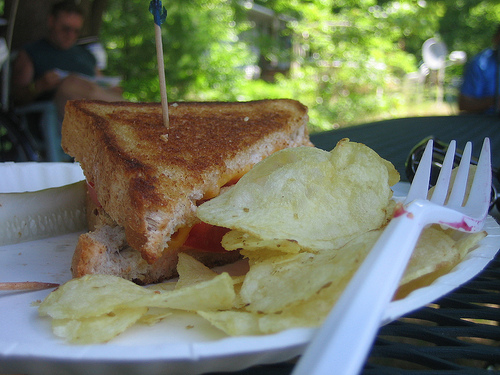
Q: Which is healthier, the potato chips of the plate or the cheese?
A: The cheese is healthier than the potato chips.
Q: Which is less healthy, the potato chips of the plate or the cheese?
A: The potato chips is less healthy than the cheese.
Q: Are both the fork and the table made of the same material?
A: No, the fork is made of plastic and the table is made of metal.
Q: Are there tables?
A: Yes, there is a table.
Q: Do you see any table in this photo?
A: Yes, there is a table.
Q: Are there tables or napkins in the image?
A: Yes, there is a table.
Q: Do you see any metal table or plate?
A: Yes, there is a metal table.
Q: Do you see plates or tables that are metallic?
A: Yes, the table is metallic.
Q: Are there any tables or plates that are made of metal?
A: Yes, the table is made of metal.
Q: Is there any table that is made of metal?
A: Yes, there is a table that is made of metal.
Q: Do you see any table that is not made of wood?
A: Yes, there is a table that is made of metal.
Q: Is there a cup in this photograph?
A: No, there are no cups.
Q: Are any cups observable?
A: No, there are no cups.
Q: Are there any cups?
A: No, there are no cups.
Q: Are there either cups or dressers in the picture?
A: No, there are no cups or dressers.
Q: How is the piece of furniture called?
A: The piece of furniture is a table.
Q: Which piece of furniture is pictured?
A: The piece of furniture is a table.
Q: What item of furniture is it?
A: The piece of furniture is a table.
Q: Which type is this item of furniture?
A: That is a table.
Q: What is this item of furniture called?
A: That is a table.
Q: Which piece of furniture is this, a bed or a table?
A: That is a table.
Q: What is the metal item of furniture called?
A: The piece of furniture is a table.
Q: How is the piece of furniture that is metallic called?
A: The piece of furniture is a table.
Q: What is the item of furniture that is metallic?
A: The piece of furniture is a table.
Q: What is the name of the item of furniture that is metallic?
A: The piece of furniture is a table.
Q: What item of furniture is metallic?
A: The piece of furniture is a table.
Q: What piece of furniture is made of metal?
A: The piece of furniture is a table.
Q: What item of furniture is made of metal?
A: The piece of furniture is a table.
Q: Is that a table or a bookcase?
A: That is a table.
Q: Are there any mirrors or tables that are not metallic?
A: No, there is a table but it is metallic.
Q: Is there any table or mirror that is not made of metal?
A: No, there is a table but it is made of metal.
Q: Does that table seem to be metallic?
A: Yes, the table is metallic.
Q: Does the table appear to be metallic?
A: Yes, the table is metallic.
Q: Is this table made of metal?
A: Yes, the table is made of metal.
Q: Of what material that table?
A: The table is made of metal.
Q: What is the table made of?
A: The table is made of metal.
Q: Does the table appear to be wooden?
A: No, the table is metallic.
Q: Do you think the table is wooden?
A: No, the table is metallic.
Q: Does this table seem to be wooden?
A: No, the table is metallic.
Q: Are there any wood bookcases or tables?
A: No, there is a table but it is metallic.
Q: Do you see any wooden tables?
A: No, there is a table but it is metallic.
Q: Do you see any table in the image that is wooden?
A: No, there is a table but it is metallic.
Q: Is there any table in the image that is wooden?
A: No, there is a table but it is metallic.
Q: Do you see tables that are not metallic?
A: No, there is a table but it is metallic.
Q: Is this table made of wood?
A: No, the table is made of metal.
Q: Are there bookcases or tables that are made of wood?
A: No, there is a table but it is made of metal.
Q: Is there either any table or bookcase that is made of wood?
A: No, there is a table but it is made of metal.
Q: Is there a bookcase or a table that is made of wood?
A: No, there is a table but it is made of metal.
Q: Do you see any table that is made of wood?
A: No, there is a table but it is made of metal.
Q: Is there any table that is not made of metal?
A: No, there is a table but it is made of metal.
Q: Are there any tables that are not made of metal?
A: No, there is a table but it is made of metal.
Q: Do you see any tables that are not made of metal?
A: No, there is a table but it is made of metal.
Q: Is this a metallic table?
A: Yes, this is a metallic table.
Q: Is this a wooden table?
A: No, this is a metallic table.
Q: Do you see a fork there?
A: Yes, there is a fork.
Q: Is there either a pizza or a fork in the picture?
A: Yes, there is a fork.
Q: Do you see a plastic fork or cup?
A: Yes, there is a plastic fork.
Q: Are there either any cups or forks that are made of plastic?
A: Yes, the fork is made of plastic.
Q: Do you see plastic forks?
A: Yes, there is a fork that is made of plastic.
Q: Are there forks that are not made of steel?
A: Yes, there is a fork that is made of plastic.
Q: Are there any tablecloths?
A: No, there are no tablecloths.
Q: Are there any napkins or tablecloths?
A: No, there are no tablecloths or napkins.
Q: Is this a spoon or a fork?
A: This is a fork.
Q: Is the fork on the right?
A: Yes, the fork is on the right of the image.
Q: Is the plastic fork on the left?
A: No, the fork is on the right of the image.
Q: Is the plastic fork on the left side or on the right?
A: The fork is on the right of the image.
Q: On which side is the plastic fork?
A: The fork is on the right of the image.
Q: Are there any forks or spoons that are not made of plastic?
A: No, there is a fork but it is made of plastic.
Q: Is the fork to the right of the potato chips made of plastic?
A: Yes, the fork is made of plastic.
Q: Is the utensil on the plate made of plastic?
A: Yes, the fork is made of plastic.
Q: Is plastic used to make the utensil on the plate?
A: Yes, the fork is made of plastic.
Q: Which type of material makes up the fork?
A: The fork is made of plastic.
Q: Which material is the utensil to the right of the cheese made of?
A: The fork is made of plastic.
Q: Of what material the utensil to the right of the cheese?
A: The fork is made of plastic.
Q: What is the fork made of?
A: The fork is made of plastic.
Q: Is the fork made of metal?
A: No, the fork is made of plastic.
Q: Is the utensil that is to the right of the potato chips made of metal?
A: No, the fork is made of plastic.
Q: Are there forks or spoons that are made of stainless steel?
A: No, there is a fork but it is made of plastic.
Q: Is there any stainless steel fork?
A: No, there is a fork but it is made of plastic.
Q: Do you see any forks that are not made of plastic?
A: No, there is a fork but it is made of plastic.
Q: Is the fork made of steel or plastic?
A: The fork is made of plastic.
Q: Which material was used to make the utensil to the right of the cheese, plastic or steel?
A: The fork is made of plastic.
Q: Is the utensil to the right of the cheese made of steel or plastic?
A: The fork is made of plastic.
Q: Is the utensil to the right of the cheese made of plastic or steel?
A: The fork is made of plastic.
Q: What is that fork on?
A: The fork is on the plate.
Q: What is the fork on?
A: The fork is on the plate.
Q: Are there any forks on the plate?
A: Yes, there is a fork on the plate.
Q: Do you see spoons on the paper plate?
A: No, there is a fork on the plate.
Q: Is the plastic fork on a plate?
A: Yes, the fork is on a plate.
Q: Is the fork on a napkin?
A: No, the fork is on a plate.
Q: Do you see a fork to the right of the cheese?
A: Yes, there is a fork to the right of the cheese.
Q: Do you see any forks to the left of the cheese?
A: No, the fork is to the right of the cheese.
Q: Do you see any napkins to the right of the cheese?
A: No, there is a fork to the right of the cheese.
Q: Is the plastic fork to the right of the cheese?
A: Yes, the fork is to the right of the cheese.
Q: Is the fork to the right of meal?
A: No, the fork is to the right of the cheese.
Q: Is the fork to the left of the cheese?
A: No, the fork is to the right of the cheese.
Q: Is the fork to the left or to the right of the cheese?
A: The fork is to the right of the cheese.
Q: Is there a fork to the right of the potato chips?
A: Yes, there is a fork to the right of the potato chips.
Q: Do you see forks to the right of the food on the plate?
A: Yes, there is a fork to the right of the potato chips.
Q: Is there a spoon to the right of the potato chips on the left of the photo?
A: No, there is a fork to the right of the potato chips.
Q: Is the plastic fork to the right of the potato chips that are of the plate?
A: Yes, the fork is to the right of the potato chips.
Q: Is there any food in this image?
A: Yes, there is food.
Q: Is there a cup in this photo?
A: No, there are no cups.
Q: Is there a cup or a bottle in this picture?
A: No, there are no cups or bottles.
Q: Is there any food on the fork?
A: Yes, there is food on the fork.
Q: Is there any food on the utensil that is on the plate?
A: Yes, there is food on the fork.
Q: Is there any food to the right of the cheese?
A: Yes, there is food to the right of the cheese.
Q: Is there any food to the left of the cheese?
A: No, the food is to the right of the cheese.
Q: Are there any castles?
A: No, there are no castles.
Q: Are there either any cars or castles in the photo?
A: No, there are no castles or cars.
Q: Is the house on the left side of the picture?
A: Yes, the house is on the left of the image.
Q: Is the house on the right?
A: No, the house is on the left of the image.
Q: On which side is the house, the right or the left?
A: The house is on the left of the image.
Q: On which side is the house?
A: The house is on the left of the image.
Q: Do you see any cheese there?
A: Yes, there is cheese.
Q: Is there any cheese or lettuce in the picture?
A: Yes, there is cheese.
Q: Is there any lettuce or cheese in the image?
A: Yes, there is cheese.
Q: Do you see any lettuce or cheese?
A: Yes, there is cheese.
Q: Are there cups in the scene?
A: No, there are no cups.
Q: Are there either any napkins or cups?
A: No, there are no cups or napkins.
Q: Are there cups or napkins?
A: No, there are no cups or napkins.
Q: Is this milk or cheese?
A: This is cheese.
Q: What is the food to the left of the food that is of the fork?
A: The food is cheese.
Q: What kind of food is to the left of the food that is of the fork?
A: The food is cheese.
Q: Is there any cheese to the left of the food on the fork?
A: Yes, there is cheese to the left of the food.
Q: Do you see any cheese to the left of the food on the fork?
A: Yes, there is cheese to the left of the food.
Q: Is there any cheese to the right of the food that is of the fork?
A: No, the cheese is to the left of the food.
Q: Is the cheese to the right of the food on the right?
A: No, the cheese is to the left of the food.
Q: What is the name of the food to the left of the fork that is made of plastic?
A: The food is cheese.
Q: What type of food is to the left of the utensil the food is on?
A: The food is cheese.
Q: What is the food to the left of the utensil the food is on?
A: The food is cheese.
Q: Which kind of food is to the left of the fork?
A: The food is cheese.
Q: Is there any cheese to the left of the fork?
A: Yes, there is cheese to the left of the fork.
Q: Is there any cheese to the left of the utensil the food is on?
A: Yes, there is cheese to the left of the fork.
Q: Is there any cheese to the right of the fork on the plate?
A: No, the cheese is to the left of the fork.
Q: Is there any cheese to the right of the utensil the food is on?
A: No, the cheese is to the left of the fork.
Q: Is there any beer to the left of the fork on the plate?
A: No, there is cheese to the left of the fork.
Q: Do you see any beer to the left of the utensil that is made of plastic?
A: No, there is cheese to the left of the fork.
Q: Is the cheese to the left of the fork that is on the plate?
A: Yes, the cheese is to the left of the fork.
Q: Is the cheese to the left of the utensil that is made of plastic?
A: Yes, the cheese is to the left of the fork.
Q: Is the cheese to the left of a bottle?
A: No, the cheese is to the left of the fork.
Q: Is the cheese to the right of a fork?
A: No, the cheese is to the left of a fork.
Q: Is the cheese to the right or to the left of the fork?
A: The cheese is to the left of the fork.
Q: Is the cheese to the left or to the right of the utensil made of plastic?
A: The cheese is to the left of the fork.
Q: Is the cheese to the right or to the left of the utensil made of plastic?
A: The cheese is to the left of the fork.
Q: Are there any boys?
A: No, there are no boys.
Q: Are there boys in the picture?
A: No, there are no boys.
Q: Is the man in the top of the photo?
A: Yes, the man is in the top of the image.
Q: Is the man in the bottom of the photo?
A: No, the man is in the top of the image.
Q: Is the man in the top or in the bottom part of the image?
A: The man is in the top of the image.